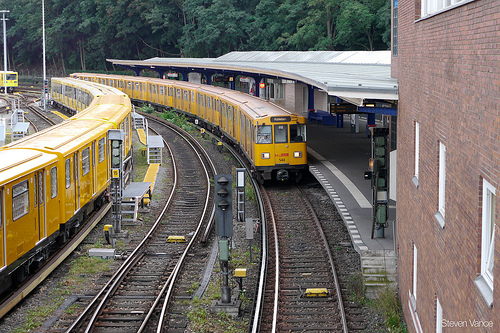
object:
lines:
[305, 145, 374, 210]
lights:
[262, 152, 270, 159]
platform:
[288, 115, 400, 253]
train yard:
[0, 70, 405, 332]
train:
[68, 70, 308, 185]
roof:
[99, 49, 400, 108]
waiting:
[305, 113, 398, 259]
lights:
[263, 152, 271, 159]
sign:
[190, 243, 283, 322]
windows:
[410, 120, 419, 188]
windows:
[437, 138, 444, 225]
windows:
[257, 125, 307, 143]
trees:
[3, 2, 388, 49]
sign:
[165, 163, 259, 284]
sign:
[5, 193, 42, 283]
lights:
[259, 82, 265, 88]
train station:
[0, 0, 398, 333]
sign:
[363, 171, 371, 181]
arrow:
[364, 175, 369, 178]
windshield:
[290, 124, 307, 143]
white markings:
[308, 165, 369, 255]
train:
[0, 75, 134, 299]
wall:
[389, 0, 500, 333]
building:
[391, 0, 496, 330]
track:
[253, 183, 349, 333]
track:
[68, 112, 218, 333]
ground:
[2, 86, 399, 332]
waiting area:
[104, 50, 398, 204]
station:
[102, 56, 398, 241]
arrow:
[213, 173, 233, 274]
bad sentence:
[102, 56, 398, 133]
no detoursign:
[86, 133, 390, 221]